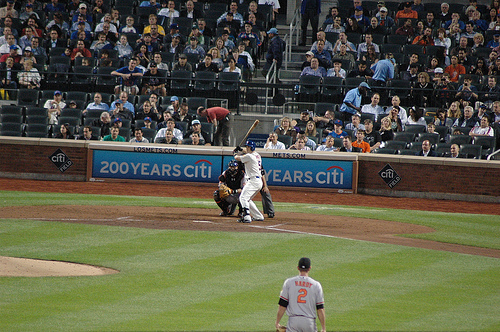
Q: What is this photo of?
A: A baseball game.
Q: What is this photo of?
A: A field.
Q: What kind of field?
A: A baseball field.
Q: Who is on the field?
A: Players.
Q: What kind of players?
A: Baseball players.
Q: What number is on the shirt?
A: The number two.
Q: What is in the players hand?
A: A bat.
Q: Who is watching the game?
A: Fans.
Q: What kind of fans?
A: Baseball fans.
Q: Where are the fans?
A: In the stands.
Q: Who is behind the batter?
A: The catcher.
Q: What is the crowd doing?
A: Watching a baseball game.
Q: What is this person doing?
A: Batting.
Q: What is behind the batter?
A: A blue banner.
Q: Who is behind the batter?
A: A catcher.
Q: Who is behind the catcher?
A: The umpire.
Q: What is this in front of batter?
A: White painted lines.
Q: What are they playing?
A: Baseball.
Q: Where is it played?
A: On a diamond.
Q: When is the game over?
A: After 9 innings unless tied.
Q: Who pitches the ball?
A: The pitcher.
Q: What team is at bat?
A: The white jerseys.